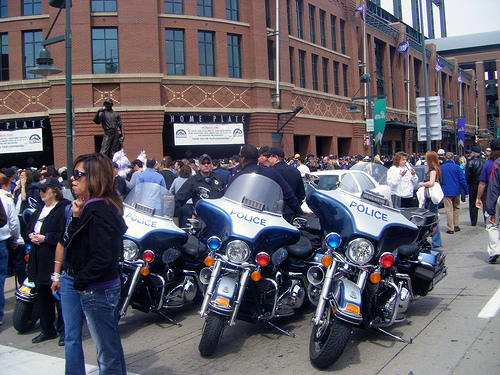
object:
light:
[326, 234, 341, 247]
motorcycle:
[305, 161, 448, 368]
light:
[328, 253, 379, 356]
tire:
[308, 315, 354, 369]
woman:
[62, 151, 127, 374]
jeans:
[78, 283, 126, 375]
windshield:
[338, 160, 403, 212]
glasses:
[74, 169, 88, 179]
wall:
[0, 0, 498, 165]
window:
[165, 27, 186, 76]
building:
[0, 0, 499, 170]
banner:
[374, 98, 387, 146]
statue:
[91, 98, 125, 160]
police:
[348, 201, 388, 222]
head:
[69, 155, 111, 196]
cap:
[33, 177, 62, 189]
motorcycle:
[194, 173, 325, 355]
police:
[174, 144, 305, 220]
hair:
[424, 150, 441, 183]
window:
[196, 28, 215, 76]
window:
[226, 30, 242, 78]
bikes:
[118, 181, 206, 327]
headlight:
[347, 237, 375, 262]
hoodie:
[61, 198, 128, 292]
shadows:
[2, 285, 444, 375]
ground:
[1, 204, 500, 373]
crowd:
[0, 147, 498, 375]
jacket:
[26, 198, 65, 286]